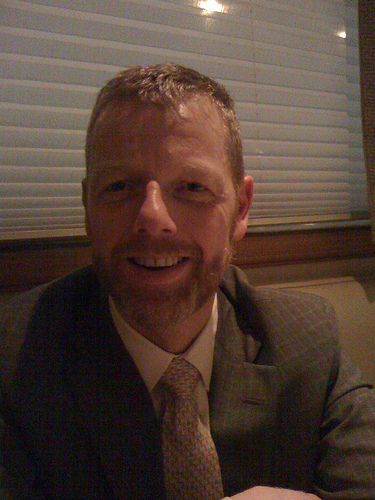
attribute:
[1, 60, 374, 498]
man — smiling, bearded, white, sitting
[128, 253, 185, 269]
teeth — upper, white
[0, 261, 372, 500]
suit — brown, dark gray, fancy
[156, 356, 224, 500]
tie — patterned, knotted, colorful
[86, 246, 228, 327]
beard — red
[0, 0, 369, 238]
blinds — closed, white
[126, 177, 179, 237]
nose — large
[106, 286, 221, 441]
shirt — white, collared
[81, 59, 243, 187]
hair — red, light brown, short